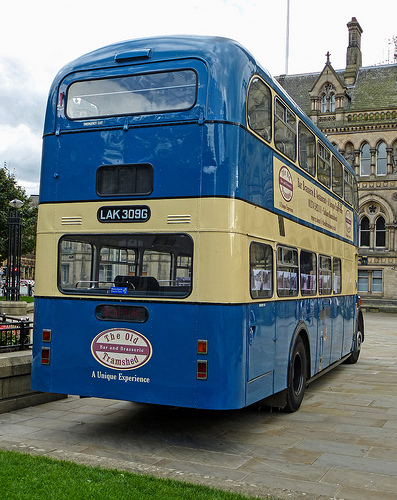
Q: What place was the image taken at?
A: It was taken at the parking lot.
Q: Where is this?
A: This is at the parking lot.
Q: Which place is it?
A: It is a parking lot.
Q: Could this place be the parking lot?
A: Yes, it is the parking lot.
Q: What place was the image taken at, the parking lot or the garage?
A: It was taken at the parking lot.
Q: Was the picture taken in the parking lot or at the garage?
A: It was taken at the parking lot.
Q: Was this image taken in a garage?
A: No, the picture was taken in a parking lot.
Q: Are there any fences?
A: Yes, there is a fence.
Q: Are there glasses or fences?
A: Yes, there is a fence.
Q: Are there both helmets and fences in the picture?
A: No, there is a fence but no helmets.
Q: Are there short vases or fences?
A: Yes, there is a short fence.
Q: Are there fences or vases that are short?
A: Yes, the fence is short.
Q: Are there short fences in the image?
A: Yes, there is a short fence.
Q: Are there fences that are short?
A: Yes, there is a fence that is short.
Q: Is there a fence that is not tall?
A: Yes, there is a short fence.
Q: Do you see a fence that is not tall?
A: Yes, there is a short fence.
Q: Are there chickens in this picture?
A: No, there are no chickens.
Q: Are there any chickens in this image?
A: No, there are no chickens.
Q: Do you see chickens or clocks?
A: No, there are no chickens or clocks.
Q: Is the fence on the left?
A: Yes, the fence is on the left of the image.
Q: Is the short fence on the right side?
A: No, the fence is on the left of the image.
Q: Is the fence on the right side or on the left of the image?
A: The fence is on the left of the image.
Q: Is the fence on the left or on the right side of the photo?
A: The fence is on the left of the image.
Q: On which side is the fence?
A: The fence is on the left of the image.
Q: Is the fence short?
A: Yes, the fence is short.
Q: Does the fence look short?
A: Yes, the fence is short.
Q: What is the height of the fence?
A: The fence is short.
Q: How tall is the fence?
A: The fence is short.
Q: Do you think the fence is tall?
A: No, the fence is short.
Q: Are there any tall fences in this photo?
A: No, there is a fence but it is short.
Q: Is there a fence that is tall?
A: No, there is a fence but it is short.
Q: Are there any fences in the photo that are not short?
A: No, there is a fence but it is short.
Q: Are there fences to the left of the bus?
A: Yes, there is a fence to the left of the bus.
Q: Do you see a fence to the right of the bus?
A: No, the fence is to the left of the bus.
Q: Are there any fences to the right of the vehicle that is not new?
A: No, the fence is to the left of the bus.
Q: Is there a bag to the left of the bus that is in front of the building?
A: No, there is a fence to the left of the bus.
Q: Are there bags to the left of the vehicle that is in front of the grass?
A: No, there is a fence to the left of the bus.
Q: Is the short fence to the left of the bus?
A: Yes, the fence is to the left of the bus.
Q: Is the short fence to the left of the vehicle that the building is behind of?
A: Yes, the fence is to the left of the bus.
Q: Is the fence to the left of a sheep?
A: No, the fence is to the left of the bus.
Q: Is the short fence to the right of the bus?
A: No, the fence is to the left of the bus.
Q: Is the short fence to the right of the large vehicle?
A: No, the fence is to the left of the bus.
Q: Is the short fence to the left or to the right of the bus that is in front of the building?
A: The fence is to the left of the bus.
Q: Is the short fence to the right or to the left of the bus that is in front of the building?
A: The fence is to the left of the bus.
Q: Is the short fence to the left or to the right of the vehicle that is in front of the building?
A: The fence is to the left of the bus.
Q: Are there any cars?
A: No, there are no cars.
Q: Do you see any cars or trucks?
A: No, there are no cars or trucks.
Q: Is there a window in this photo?
A: Yes, there is a window.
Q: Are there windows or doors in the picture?
A: Yes, there is a window.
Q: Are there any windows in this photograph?
A: Yes, there is a window.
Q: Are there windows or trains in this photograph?
A: Yes, there is a window.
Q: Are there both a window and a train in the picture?
A: No, there is a window but no trains.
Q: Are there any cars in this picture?
A: No, there are no cars.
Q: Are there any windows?
A: Yes, there is a window.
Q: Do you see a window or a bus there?
A: Yes, there is a window.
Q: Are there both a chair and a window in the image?
A: No, there is a window but no chairs.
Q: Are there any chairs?
A: No, there are no chairs.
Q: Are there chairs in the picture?
A: No, there are no chairs.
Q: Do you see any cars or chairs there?
A: No, there are no chairs or cars.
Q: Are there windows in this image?
A: Yes, there is a window.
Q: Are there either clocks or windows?
A: Yes, there is a window.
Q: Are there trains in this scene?
A: No, there are no trains.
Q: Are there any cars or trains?
A: No, there are no trains or cars.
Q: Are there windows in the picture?
A: Yes, there is a window.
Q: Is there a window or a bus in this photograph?
A: Yes, there is a window.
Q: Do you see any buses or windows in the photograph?
A: Yes, there is a window.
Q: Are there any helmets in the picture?
A: No, there are no helmets.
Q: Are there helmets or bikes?
A: No, there are no helmets or bikes.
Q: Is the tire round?
A: Yes, the tire is round.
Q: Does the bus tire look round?
A: Yes, the tire is round.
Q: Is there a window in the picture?
A: Yes, there is a window.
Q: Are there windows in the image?
A: Yes, there is a window.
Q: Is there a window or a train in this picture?
A: Yes, there is a window.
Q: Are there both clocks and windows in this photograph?
A: No, there is a window but no clocks.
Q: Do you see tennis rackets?
A: No, there are no tennis rackets.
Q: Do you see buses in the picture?
A: Yes, there is a bus.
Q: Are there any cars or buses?
A: Yes, there is a bus.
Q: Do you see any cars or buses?
A: Yes, there is a bus.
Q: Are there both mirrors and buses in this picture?
A: Yes, there are both a bus and a mirror.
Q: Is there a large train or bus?
A: Yes, there is a large bus.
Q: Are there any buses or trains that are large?
A: Yes, the bus is large.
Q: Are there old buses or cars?
A: Yes, there is an old bus.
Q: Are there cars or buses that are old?
A: Yes, the bus is old.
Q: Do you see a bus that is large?
A: Yes, there is a large bus.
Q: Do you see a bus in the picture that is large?
A: Yes, there is a bus that is large.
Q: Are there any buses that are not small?
A: Yes, there is a large bus.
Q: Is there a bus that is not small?
A: Yes, there is a large bus.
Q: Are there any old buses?
A: Yes, there is an old bus.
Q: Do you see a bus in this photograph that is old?
A: Yes, there is a bus that is old.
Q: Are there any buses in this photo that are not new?
A: Yes, there is a old bus.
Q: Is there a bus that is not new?
A: Yes, there is a old bus.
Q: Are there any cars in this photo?
A: No, there are no cars.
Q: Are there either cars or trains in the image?
A: No, there are no cars or trains.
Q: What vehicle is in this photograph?
A: The vehicle is a bus.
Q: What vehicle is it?
A: The vehicle is a bus.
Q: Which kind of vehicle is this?
A: This is a bus.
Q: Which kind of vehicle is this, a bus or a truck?
A: This is a bus.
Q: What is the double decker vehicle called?
A: The vehicle is a bus.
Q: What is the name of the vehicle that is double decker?
A: The vehicle is a bus.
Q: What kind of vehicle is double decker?
A: The vehicle is a bus.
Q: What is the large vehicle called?
A: The vehicle is a bus.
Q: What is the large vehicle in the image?
A: The vehicle is a bus.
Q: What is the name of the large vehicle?
A: The vehicle is a bus.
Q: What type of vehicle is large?
A: The vehicle is a bus.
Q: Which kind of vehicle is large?
A: The vehicle is a bus.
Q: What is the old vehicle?
A: The vehicle is a bus.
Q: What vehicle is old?
A: The vehicle is a bus.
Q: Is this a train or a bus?
A: This is a bus.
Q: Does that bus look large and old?
A: Yes, the bus is large and old.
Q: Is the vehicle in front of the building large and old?
A: Yes, the bus is large and old.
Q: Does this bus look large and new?
A: No, the bus is large but old.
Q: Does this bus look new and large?
A: No, the bus is large but old.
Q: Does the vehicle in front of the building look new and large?
A: No, the bus is large but old.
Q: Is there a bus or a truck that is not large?
A: No, there is a bus but it is large.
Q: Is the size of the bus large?
A: Yes, the bus is large.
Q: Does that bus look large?
A: Yes, the bus is large.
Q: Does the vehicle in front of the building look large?
A: Yes, the bus is large.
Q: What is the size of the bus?
A: The bus is large.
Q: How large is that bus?
A: The bus is large.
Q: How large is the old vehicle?
A: The bus is large.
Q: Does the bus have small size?
A: No, the bus is large.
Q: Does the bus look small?
A: No, the bus is large.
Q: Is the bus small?
A: No, the bus is large.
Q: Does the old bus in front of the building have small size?
A: No, the bus is large.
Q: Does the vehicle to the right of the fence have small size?
A: No, the bus is large.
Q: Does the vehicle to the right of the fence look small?
A: No, the bus is large.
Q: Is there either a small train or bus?
A: No, there is a bus but it is large.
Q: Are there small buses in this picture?
A: No, there is a bus but it is large.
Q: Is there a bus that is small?
A: No, there is a bus but it is large.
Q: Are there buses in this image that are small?
A: No, there is a bus but it is large.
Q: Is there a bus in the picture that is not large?
A: No, there is a bus but it is large.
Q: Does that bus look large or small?
A: The bus is large.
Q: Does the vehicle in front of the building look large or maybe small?
A: The bus is large.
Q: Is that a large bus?
A: Yes, that is a large bus.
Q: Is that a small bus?
A: No, that is a large bus.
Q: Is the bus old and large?
A: Yes, the bus is old and large.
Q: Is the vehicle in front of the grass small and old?
A: No, the bus is old but large.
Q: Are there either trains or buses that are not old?
A: No, there is a bus but it is old.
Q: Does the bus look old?
A: Yes, the bus is old.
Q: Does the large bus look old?
A: Yes, the bus is old.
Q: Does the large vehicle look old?
A: Yes, the bus is old.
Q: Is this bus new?
A: No, the bus is old.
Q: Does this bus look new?
A: No, the bus is old.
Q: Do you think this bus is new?
A: No, the bus is old.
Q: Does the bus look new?
A: No, the bus is old.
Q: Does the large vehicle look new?
A: No, the bus is old.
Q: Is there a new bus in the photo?
A: No, there is a bus but it is old.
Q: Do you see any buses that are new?
A: No, there is a bus but it is old.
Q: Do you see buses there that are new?
A: No, there is a bus but it is old.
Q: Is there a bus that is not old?
A: No, there is a bus but it is old.